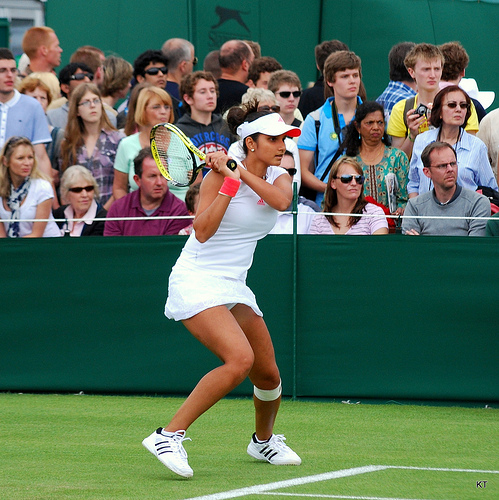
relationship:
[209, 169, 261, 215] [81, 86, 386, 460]
wristband on tennis player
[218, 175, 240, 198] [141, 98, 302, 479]
wristband on a female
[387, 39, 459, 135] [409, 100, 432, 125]
man holding camera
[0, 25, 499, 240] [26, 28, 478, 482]
spectator watching match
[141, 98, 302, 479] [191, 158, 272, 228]
female wearing wristband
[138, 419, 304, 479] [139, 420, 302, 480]
tennis shoes has pins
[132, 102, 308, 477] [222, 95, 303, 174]
female has head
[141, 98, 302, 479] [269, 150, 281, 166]
female has mouth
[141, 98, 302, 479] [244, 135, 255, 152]
female has ear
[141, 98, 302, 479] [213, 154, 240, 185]
female has hand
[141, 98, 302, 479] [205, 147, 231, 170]
female has hand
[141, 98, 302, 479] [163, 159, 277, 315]
female has dress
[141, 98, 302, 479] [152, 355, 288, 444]
female has shins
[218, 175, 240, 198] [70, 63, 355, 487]
wristband on player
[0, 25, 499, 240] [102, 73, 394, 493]
spectator watch match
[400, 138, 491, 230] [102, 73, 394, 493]
spectator watch match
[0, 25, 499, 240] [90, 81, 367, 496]
spectator watch match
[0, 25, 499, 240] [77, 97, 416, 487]
spectator watch match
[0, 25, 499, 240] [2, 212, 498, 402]
spectator in bleachers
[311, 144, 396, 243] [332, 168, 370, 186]
woman wear sunglasses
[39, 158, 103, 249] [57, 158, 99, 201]
woman has hair